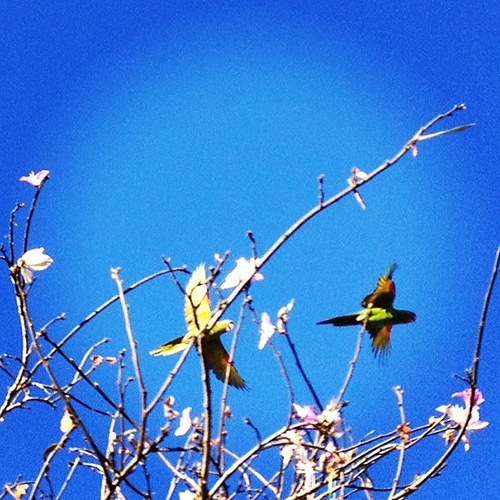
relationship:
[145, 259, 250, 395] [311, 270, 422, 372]
bird flying with bird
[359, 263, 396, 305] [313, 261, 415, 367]
wing on bird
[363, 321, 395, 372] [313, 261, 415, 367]
wing on bird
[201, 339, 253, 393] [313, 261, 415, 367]
wing on bird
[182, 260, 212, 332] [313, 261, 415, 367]
wing on bird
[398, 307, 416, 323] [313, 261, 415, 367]
head of bird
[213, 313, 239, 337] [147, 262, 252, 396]
head of bird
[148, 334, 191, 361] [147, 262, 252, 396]
tail of bird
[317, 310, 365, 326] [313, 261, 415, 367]
tail of bird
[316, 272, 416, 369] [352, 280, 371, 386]
bird on a branch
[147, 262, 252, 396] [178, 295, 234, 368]
bird on a branch